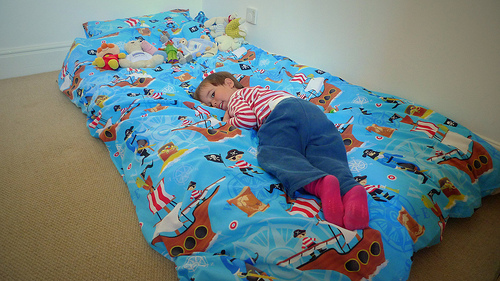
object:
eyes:
[205, 76, 227, 117]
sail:
[146, 176, 185, 241]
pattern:
[121, 59, 203, 191]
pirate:
[354, 175, 396, 203]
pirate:
[292, 228, 328, 261]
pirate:
[186, 180, 207, 205]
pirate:
[225, 149, 264, 178]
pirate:
[143, 88, 178, 105]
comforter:
[48, 5, 499, 277]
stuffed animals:
[91, 10, 248, 70]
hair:
[193, 70, 244, 100]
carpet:
[0, 77, 160, 281]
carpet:
[401, 198, 498, 275]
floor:
[414, 189, 499, 281]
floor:
[0, 77, 175, 281]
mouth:
[218, 101, 225, 110]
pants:
[256, 97, 364, 200]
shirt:
[227, 85, 297, 131]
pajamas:
[225, 87, 298, 131]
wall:
[0, 0, 203, 80]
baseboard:
[0, 44, 77, 80]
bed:
[55, 10, 499, 279]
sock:
[304, 175, 345, 228]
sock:
[342, 184, 370, 230]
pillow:
[74, 26, 166, 55]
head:
[193, 70, 244, 110]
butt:
[271, 96, 341, 136]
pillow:
[82, 8, 194, 39]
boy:
[192, 70, 370, 231]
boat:
[131, 158, 221, 259]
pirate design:
[67, 12, 498, 281]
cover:
[55, 10, 499, 281]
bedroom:
[0, 0, 500, 281]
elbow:
[241, 117, 257, 128]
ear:
[224, 78, 235, 89]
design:
[149, 185, 220, 257]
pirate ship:
[295, 219, 387, 280]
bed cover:
[55, 10, 499, 280]